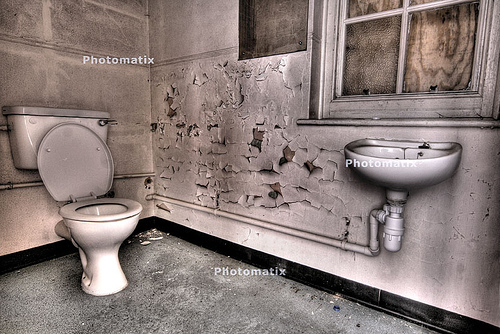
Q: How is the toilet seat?
A: Opened.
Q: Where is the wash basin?
A: Fixed on the wall.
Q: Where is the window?
A: On top of the wash basin.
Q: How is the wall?
A: Dirty and broken.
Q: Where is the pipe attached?
A: To the washbasin.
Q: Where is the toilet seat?
A: In the bathroom.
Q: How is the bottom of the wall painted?
A: Black.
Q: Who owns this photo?
A: Photomatix.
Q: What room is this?
A: Bathroom.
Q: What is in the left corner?
A: Toilet.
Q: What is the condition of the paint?
A: Peeling.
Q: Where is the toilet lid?
A: Up.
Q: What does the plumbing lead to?
A: Sink.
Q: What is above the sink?
A: Window.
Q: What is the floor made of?
A: Cement.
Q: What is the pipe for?
A: Plumbing.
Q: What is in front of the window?
A: Wooden board.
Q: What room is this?
A: Bathroom.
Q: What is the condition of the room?
A: Dirty.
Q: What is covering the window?
A: Wood.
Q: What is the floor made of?
A: Concrete.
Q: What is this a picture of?
A: Bathroom.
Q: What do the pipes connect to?
A: Plumbing.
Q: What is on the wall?
A: Sink.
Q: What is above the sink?
A: Window.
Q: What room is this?
A: A bathroom.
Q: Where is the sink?
A: Under the window.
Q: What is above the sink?
A: The window.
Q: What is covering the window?
A: Plywood board.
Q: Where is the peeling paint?
A: On the wall.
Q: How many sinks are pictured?
A: One.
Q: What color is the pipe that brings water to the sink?
A: White.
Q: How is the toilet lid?
A: It's open.